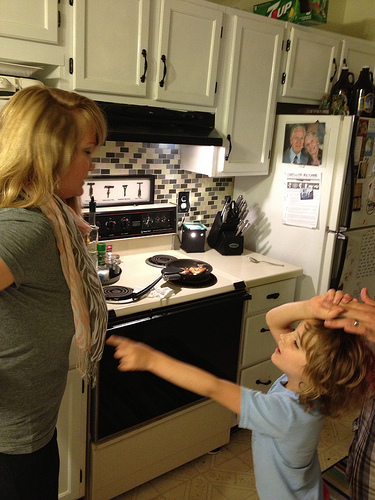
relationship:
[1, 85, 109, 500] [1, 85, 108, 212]
woman has hair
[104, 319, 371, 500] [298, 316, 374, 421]
child has hair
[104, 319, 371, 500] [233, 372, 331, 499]
child wearing shirt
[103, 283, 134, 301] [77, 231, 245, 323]
burner on top of stove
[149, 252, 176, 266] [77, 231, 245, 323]
burner on top of stove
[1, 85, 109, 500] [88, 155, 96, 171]
woman has nose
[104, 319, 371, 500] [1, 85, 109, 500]
child pointing at woman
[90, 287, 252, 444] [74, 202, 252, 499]
door on front of oven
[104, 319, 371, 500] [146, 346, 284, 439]
child has arm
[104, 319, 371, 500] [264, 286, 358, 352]
child has arm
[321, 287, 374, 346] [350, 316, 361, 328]
hand wearing ring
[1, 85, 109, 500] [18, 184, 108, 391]
woman wearing scarf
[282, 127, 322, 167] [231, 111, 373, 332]
couple on side of refrigerator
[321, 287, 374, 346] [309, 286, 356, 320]
hand holding hand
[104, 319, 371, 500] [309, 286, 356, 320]
child has hand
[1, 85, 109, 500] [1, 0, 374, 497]
woman standing in kitchen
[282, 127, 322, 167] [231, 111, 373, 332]
couple posted on refrigerator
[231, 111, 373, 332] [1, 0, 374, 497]
refrigerator standing in kitchen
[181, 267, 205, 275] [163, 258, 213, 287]
food on top of frying pan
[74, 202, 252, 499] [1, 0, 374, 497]
oven inside of kitchen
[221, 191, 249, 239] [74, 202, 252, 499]
knives next to oven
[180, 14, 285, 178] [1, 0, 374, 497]
cabinet inside of kitchen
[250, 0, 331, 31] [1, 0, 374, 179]
box on top of cabinets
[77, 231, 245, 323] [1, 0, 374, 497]
stove inside of kitchen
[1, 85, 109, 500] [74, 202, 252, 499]
woman standing by oven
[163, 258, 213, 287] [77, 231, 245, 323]
frying pan sitting on stove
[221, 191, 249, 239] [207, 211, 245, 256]
knives inside of knife box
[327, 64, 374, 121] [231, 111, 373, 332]
bottles on top of refrigerator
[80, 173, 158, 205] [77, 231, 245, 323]
picture on top of stove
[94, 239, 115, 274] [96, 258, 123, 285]
spices on top of tray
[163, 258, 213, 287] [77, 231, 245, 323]
frying pan on top of stove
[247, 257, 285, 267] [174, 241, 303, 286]
spoon on top of counter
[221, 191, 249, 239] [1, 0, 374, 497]
knives inside of kitchen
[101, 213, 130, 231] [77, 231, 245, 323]
control knobs on top of stove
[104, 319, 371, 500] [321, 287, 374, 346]
child holding hand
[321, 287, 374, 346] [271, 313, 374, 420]
hand on top of head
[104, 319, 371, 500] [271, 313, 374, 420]
child has head